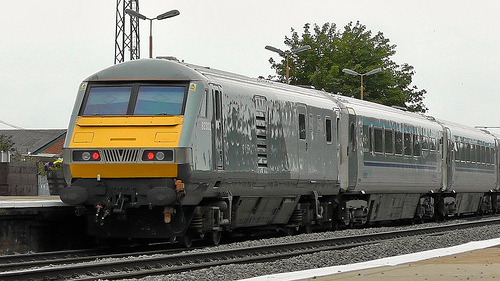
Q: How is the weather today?
A: It is foggy.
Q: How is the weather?
A: It is foggy.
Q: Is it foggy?
A: Yes, it is foggy.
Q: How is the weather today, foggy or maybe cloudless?
A: It is foggy.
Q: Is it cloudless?
A: No, it is foggy.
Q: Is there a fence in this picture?
A: No, there are no fences.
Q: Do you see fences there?
A: No, there are no fences.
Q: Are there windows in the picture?
A: Yes, there is a window.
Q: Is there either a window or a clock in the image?
A: Yes, there is a window.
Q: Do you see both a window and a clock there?
A: No, there is a window but no clocks.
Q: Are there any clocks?
A: No, there are no clocks.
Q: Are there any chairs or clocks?
A: No, there are no clocks or chairs.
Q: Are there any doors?
A: Yes, there is a door.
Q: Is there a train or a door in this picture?
A: Yes, there is a door.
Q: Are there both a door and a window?
A: Yes, there are both a door and a window.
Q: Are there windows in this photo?
A: Yes, there are windows.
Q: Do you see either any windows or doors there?
A: Yes, there are windows.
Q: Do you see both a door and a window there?
A: Yes, there are both a window and a door.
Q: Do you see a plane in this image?
A: No, there are no airplanes.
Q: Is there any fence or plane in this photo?
A: No, there are no airplanes or fences.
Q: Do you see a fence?
A: No, there are no fences.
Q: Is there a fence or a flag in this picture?
A: No, there are no fences or flags.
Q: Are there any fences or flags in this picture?
A: No, there are no fences or flags.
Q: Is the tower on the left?
A: Yes, the tower is on the left of the image.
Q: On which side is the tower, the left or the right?
A: The tower is on the left of the image.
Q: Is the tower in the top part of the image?
A: Yes, the tower is in the top of the image.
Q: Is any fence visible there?
A: No, there are no fences.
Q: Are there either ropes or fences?
A: No, there are no fences or ropes.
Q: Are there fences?
A: No, there are no fences.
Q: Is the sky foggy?
A: Yes, the sky is foggy.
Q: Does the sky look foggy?
A: Yes, the sky is foggy.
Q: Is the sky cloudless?
A: No, the sky is foggy.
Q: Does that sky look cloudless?
A: No, the sky is foggy.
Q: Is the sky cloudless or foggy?
A: The sky is foggy.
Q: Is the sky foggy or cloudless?
A: The sky is foggy.